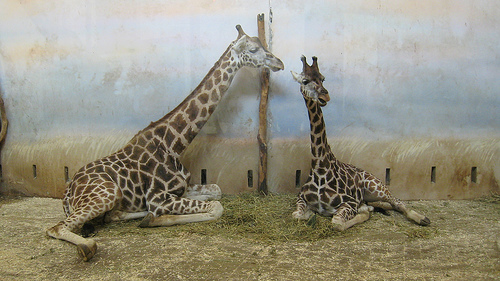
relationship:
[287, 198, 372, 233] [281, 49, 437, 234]
legs of zebra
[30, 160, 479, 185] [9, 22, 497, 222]
lines in wall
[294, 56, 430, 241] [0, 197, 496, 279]
giraffe sitting on ground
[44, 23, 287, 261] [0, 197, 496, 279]
giraffe sitting on ground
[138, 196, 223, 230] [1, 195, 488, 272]
leg on ground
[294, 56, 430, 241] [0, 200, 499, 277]
giraffe on field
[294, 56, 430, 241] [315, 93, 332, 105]
giraffe has mouth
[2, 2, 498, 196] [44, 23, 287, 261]
wall behind giraffe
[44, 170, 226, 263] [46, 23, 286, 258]
legs on giraffe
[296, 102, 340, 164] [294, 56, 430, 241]
long neck on giraffe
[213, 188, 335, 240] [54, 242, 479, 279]
hay on ground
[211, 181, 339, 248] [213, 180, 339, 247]
hay in pile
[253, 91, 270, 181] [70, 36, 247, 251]
wood behind giraffe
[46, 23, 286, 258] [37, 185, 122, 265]
giraffe has leg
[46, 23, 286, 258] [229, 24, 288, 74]
giraffe has head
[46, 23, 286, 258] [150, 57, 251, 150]
giraffe has long neck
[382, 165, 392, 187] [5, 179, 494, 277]
post in field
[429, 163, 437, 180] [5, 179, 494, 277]
post in field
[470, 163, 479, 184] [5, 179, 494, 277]
post in field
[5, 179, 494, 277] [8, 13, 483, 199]
field on painting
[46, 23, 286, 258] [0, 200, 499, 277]
giraffe sitting on field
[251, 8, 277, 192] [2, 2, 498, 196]
pole next to wall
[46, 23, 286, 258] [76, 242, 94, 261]
giraffe has hoof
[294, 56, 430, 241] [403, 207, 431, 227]
giraffe has hoof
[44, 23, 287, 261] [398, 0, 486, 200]
giraffe in front of painted wall